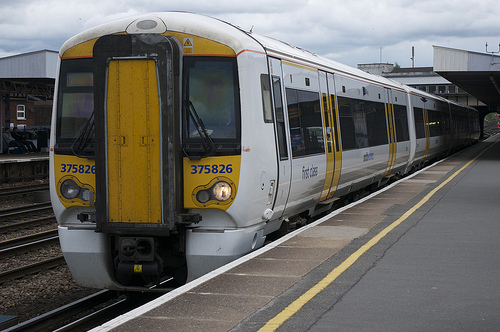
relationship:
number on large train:
[187, 161, 233, 173] [49, 11, 484, 294]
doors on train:
[318, 71, 340, 203] [51, 7, 435, 217]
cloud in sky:
[361, 8, 477, 37] [2, 4, 498, 79]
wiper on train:
[182, 102, 213, 156] [55, 17, 294, 234]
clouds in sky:
[231, 4, 498, 64] [257, 1, 484, 49]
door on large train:
[106, 58, 162, 224] [49, 11, 484, 294]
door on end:
[106, 62, 161, 227] [58, 29, 262, 286]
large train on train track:
[45, 8, 483, 293] [2, 284, 150, 329]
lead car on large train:
[40, 12, 301, 284] [49, 11, 484, 294]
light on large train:
[212, 181, 232, 201] [49, 11, 484, 294]